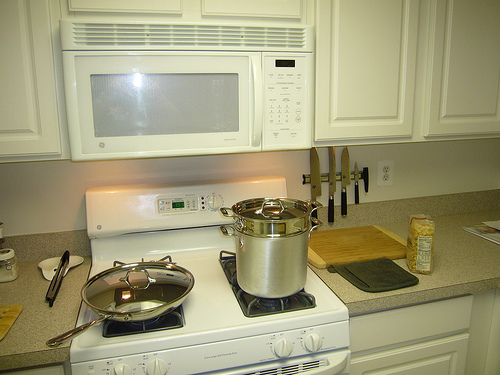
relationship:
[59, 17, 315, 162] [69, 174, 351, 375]
microwave over stove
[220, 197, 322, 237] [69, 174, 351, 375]
pot on stove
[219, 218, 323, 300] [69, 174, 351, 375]
pot on stove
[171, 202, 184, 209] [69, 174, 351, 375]
clock on stove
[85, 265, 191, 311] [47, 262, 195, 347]
lid on pan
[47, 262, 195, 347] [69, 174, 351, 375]
pan on stove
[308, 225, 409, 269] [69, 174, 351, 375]
chopping board to right of stove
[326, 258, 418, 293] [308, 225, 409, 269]
hot pad in front of chopping board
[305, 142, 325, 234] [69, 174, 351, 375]
knives next to stove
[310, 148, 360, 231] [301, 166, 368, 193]
knives hanging on knife holder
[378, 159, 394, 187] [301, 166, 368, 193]
electrical outlet next to knife holder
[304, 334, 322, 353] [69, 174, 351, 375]
knob on stove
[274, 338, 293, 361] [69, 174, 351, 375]
knob on stove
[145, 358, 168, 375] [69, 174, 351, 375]
knob on stove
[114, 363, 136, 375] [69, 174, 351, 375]
knob on stove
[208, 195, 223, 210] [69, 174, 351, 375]
knob on stove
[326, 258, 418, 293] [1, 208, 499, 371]
hot pad on counter top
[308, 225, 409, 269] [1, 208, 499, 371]
chopping board on counter top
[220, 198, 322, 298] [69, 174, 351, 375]
double boiler on stove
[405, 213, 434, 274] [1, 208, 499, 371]
bag of pasta on counter top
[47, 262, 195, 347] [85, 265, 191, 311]
pan under lid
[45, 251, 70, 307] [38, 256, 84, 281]
tongs are resting on spoon rest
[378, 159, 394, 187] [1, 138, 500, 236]
electrical outlet on wall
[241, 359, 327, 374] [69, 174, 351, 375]
vent on stove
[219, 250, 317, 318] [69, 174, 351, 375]
burner on stove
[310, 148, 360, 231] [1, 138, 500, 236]
knives are on wall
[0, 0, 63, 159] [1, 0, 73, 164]
door on cabinet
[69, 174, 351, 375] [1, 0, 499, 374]
stove in kitchen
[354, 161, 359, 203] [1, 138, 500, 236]
knife on wall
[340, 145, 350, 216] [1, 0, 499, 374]
knife in kitchen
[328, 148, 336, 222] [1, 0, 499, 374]
knife in kitchen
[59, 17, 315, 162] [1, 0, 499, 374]
microwave in kitchen